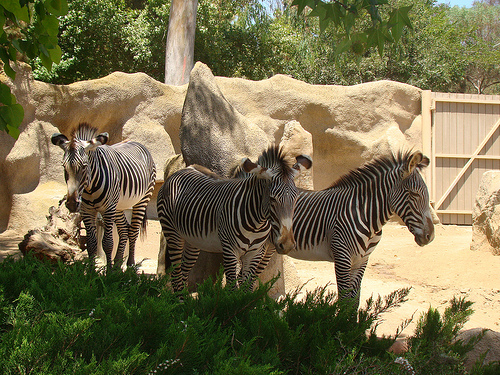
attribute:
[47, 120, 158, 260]
zebra — fenced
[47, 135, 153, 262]
zebra — white , black 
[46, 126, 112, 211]
head — white 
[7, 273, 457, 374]
bush — evergreen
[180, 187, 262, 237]
stripes — black , white 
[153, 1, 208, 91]
tree trunk — gray 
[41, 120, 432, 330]
zebras — fenced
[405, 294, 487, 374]
shrubbery — green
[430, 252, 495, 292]
ground — sandy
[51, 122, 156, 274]
zebra — fenced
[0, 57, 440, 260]
boulder — tan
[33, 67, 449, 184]
wall — stone, tan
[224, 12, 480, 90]
trees — green 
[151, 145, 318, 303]
stripes — white, black 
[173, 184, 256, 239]
strips — white , black 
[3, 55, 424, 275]
wall — big, rock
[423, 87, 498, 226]
gate — tan, wooden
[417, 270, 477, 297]
dirt ground — tan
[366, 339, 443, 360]
trash — small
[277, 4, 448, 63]
leaves — small, green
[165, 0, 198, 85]
tree — tan, wooden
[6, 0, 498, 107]
trees — green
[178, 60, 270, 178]
rock — big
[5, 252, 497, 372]
bush — green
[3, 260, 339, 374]
bushes — green 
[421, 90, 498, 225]
fence — tan, wood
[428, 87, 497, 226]
door — tan, wooden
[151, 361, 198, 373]
pine cone — small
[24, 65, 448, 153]
wall — rock